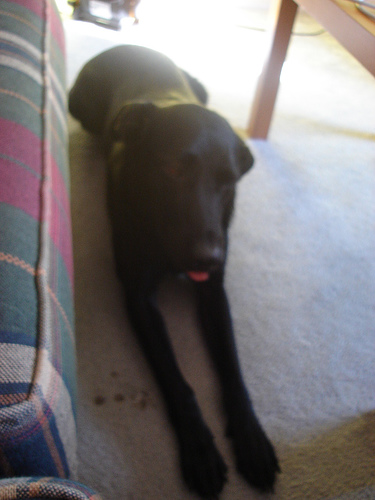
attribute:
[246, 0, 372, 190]
chair — edge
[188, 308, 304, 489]
leg — edge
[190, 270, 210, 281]
tongue — pink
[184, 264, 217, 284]
tongue — dogs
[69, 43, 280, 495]
dog — black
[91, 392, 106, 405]
stain — brown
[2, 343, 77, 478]
stripe — beige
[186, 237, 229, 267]
nose — black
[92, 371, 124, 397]
stain — red 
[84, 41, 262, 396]
dog — black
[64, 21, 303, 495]
dog — black, big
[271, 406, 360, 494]
trim — brown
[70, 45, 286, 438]
dog — all black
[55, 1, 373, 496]
floor — part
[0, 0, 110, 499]
couch — blue, stripe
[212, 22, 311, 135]
cord — electrical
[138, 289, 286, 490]
legs — black, long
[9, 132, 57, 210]
stripe — pink